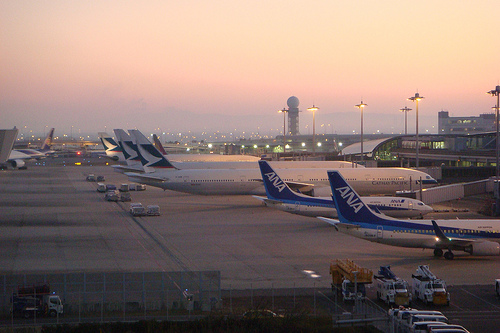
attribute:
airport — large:
[19, 93, 486, 324]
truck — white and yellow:
[308, 241, 391, 331]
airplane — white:
[119, 128, 439, 210]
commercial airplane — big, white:
[104, 125, 441, 202]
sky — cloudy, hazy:
[4, 2, 495, 144]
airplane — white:
[325, 167, 496, 258]